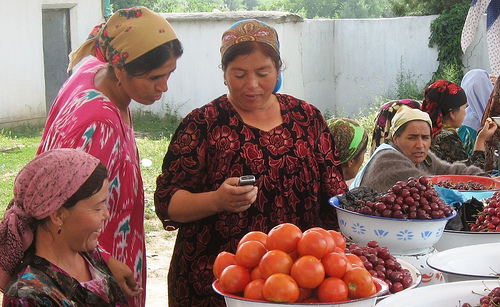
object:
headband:
[67, 5, 181, 62]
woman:
[455, 68, 500, 154]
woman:
[348, 99, 498, 193]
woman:
[421, 79, 498, 169]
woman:
[37, 5, 182, 305]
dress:
[153, 92, 350, 306]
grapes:
[392, 281, 402, 293]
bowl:
[377, 258, 423, 300]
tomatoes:
[340, 267, 373, 301]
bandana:
[369, 98, 433, 160]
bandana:
[219, 19, 283, 94]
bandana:
[0, 148, 101, 293]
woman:
[0, 147, 127, 307]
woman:
[324, 117, 369, 181]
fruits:
[363, 206, 376, 215]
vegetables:
[213, 252, 236, 280]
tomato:
[265, 223, 302, 254]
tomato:
[296, 231, 327, 260]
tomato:
[290, 254, 325, 289]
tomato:
[259, 250, 292, 280]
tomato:
[237, 239, 268, 270]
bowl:
[212, 276, 390, 306]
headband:
[422, 80, 467, 135]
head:
[423, 79, 470, 130]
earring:
[56, 224, 62, 234]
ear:
[112, 63, 124, 82]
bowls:
[390, 246, 448, 288]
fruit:
[219, 265, 251, 294]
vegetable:
[235, 230, 268, 250]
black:
[239, 175, 255, 186]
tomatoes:
[259, 249, 295, 281]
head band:
[324, 118, 369, 165]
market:
[1, 4, 500, 307]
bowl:
[424, 241, 500, 283]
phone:
[238, 174, 256, 185]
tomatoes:
[317, 277, 347, 302]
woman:
[153, 18, 350, 307]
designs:
[340, 219, 347, 226]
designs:
[351, 222, 366, 236]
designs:
[373, 229, 389, 236]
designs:
[396, 229, 414, 241]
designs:
[420, 230, 432, 240]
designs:
[435, 226, 444, 240]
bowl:
[328, 190, 457, 256]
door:
[41, 8, 73, 123]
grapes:
[378, 247, 390, 260]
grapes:
[487, 208, 496, 217]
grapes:
[377, 271, 386, 279]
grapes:
[490, 297, 500, 303]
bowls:
[433, 229, 499, 252]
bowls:
[376, 278, 500, 307]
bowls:
[431, 174, 495, 202]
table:
[211, 149, 500, 307]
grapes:
[404, 196, 414, 204]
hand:
[219, 176, 257, 213]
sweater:
[349, 141, 486, 195]